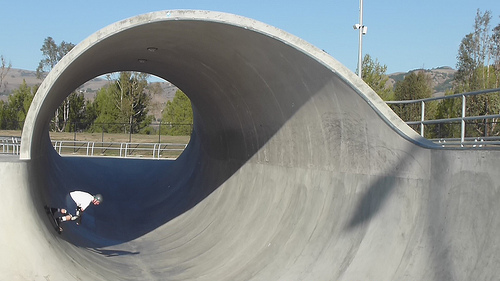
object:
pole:
[375, 85, 440, 108]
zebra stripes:
[413, 92, 434, 140]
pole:
[89, 140, 96, 155]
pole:
[118, 142, 122, 157]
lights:
[132, 43, 167, 70]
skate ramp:
[152, 22, 497, 279]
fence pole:
[455, 95, 464, 143]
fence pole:
[421, 98, 426, 135]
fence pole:
[397, 85, 499, 107]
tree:
[306, 17, 492, 92]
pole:
[460, 91, 467, 145]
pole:
[419, 97, 425, 138]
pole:
[412, 92, 447, 149]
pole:
[53, 136, 63, 153]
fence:
[52, 137, 192, 156]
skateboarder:
[51, 177, 118, 234]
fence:
[381, 85, 496, 131]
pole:
[421, 86, 463, 108]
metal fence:
[386, 86, 498, 146]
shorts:
[62, 190, 79, 219]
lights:
[351, 22, 372, 35]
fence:
[0, 91, 495, 151]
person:
[33, 133, 134, 242]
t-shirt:
[67, 186, 96, 215]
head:
[90, 192, 106, 209]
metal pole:
[151, 142, 161, 157]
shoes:
[38, 195, 72, 244]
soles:
[43, 197, 62, 239]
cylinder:
[77, 52, 352, 279]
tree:
[454, 15, 485, 144]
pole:
[359, 2, 363, 78]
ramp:
[0, 11, 499, 277]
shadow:
[93, 246, 143, 262]